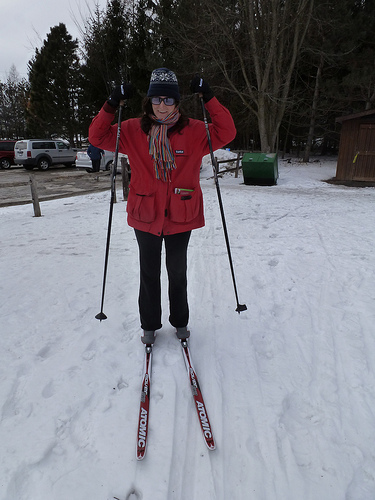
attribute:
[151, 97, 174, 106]
goggles —  a pair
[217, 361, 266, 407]
tracks — ski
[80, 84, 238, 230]
jacket — red 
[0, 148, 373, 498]
snow — white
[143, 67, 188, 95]
hat — Knit 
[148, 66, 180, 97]
hat — gray 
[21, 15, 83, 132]
pine tree — tall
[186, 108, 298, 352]
pole — black, ski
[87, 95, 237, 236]
jacket — red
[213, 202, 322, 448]
snow — white